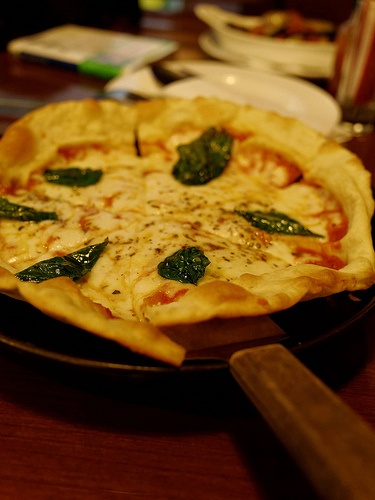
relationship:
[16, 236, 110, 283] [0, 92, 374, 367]
basil leaf on pizza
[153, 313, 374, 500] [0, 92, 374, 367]
server under pizza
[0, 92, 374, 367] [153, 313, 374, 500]
pizza on top of server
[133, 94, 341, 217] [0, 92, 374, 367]
slice of pizza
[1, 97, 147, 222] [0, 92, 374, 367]
slice of pizza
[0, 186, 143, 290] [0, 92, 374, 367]
slice of pizza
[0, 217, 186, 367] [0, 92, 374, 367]
slice of pizza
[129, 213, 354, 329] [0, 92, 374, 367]
slice of pizza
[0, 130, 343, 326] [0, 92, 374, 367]
cheese on pizza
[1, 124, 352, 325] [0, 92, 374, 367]
toppings on top pizza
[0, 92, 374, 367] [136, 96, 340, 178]
pizza has crust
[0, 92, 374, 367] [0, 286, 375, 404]
pizza on pizza dish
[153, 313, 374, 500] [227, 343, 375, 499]
pizza server has handle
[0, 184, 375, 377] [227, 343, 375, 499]
pizza dish has handle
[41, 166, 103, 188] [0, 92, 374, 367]
leaf spice on pizza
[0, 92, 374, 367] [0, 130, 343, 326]
pizza has cheese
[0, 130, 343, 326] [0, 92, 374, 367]
cheese on top pizza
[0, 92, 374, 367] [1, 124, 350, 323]
pizza has tomato sauce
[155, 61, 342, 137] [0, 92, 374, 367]
plate behind pizza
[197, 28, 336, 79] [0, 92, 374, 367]
plate behind pizza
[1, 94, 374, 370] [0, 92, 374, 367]
crust on pizza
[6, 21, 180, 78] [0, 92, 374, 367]
book behind pizza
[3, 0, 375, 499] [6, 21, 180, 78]
table has a book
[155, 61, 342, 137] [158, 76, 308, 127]
plate with napkin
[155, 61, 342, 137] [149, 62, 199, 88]
plate with utensils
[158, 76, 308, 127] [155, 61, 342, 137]
napkin in plate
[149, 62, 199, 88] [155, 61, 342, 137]
utensils in plate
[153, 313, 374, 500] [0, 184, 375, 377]
spatula on pan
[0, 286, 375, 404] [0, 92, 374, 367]
pizza dish under pizza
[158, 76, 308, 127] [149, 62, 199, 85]
napkin with utensils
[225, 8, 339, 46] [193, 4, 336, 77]
food in plate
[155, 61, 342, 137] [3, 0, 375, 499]
plate on table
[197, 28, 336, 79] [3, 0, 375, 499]
plate on table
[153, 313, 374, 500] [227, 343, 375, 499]
spatula has handle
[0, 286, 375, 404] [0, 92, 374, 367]
pizza dish has pizza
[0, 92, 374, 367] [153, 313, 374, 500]
pizza on top of spatula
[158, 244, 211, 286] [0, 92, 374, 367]
spinach on pizza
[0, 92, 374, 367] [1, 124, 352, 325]
pizza has seasoning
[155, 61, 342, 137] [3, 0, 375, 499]
plate on top table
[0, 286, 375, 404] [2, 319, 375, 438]
pizza dish has shadow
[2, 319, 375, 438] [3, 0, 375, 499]
shadow on table